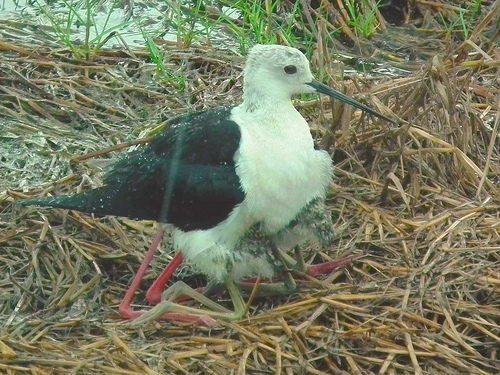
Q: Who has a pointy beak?
A: The bird.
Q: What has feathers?
A: Bird.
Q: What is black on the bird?
A: Tail.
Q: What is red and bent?
A: Legs.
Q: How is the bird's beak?
A: Long and pointed.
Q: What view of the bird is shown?
A: The side.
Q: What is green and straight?
A: Grass.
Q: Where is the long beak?
A: On the bird.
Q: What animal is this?
A: Bird.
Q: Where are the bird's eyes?
A: On the head.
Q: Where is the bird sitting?
A: In a nest.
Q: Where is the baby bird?
A: Hiding under the bigger bird.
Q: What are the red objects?
A: Bird legs.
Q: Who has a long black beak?
A: The bird.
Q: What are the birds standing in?
A: Dried grass.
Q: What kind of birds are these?
A: Sandpipers.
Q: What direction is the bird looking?
A: Right.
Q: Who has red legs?
A: The large bird.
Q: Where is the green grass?
A: Behind the birds.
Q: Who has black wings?
A: The adult bird.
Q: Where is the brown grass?
A: Under the birds.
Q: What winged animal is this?
A: Bird.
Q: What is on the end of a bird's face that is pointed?
A: Beak.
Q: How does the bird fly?
A: Wings.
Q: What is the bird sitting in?
A: Nest.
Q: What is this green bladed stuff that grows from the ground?
A: Grass.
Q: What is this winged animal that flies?
A: Bird.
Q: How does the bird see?
A: Eyes.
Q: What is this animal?
A: A bird.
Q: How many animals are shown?
A: One.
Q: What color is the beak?
A: Black.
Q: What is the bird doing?
A: Standing.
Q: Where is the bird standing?
A: In the straw.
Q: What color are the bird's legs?
A: Red.